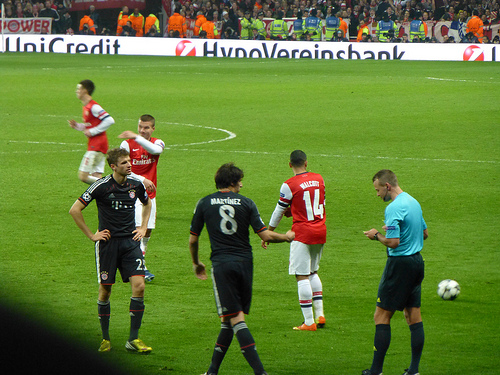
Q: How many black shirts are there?
A: 2.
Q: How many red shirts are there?
A: 3.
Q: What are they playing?
A: Soccer.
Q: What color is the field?
A: Green.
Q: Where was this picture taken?
A: Soccer field.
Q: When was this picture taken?
A: Daytime.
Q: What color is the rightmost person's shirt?
A: Blue.